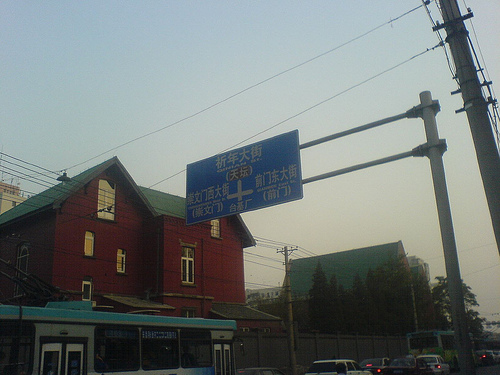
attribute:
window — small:
[81, 276, 91, 300]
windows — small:
[207, 342, 237, 370]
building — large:
[0, 159, 254, 369]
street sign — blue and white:
[179, 126, 308, 221]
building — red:
[24, 166, 183, 298]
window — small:
[205, 215, 224, 238]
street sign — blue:
[186, 121, 305, 211]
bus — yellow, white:
[404, 325, 462, 372]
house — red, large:
[10, 164, 253, 311]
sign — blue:
[144, 327, 182, 345]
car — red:
[359, 351, 439, 372]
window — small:
[79, 227, 104, 261]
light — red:
[368, 365, 377, 372]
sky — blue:
[1, 4, 499, 329]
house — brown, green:
[6, 154, 255, 324]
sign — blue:
[177, 124, 311, 220]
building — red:
[2, 149, 260, 325]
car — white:
[306, 351, 367, 372]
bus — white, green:
[397, 327, 484, 372]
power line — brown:
[277, 244, 307, 373]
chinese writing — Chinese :
[204, 155, 305, 205]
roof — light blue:
[0, 303, 241, 323]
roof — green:
[0, 156, 260, 245]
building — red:
[0, 148, 276, 371]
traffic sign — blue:
[179, 126, 306, 224]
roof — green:
[283, 238, 416, 303]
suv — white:
[316, 350, 368, 373]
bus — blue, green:
[406, 324, 498, 371]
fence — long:
[240, 324, 409, 373]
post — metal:
[299, 88, 473, 371]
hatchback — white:
[411, 349, 452, 373]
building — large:
[3, 147, 248, 373]